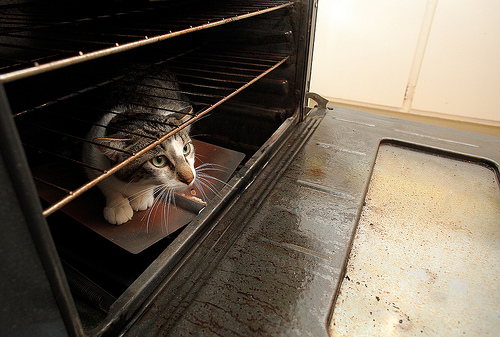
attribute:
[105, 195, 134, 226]
paw — white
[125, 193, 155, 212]
paw — white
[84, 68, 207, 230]
cat — hiding, striped, black, white, looking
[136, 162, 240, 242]
whiskers — white, long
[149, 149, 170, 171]
eye — yellow green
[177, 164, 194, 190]
nose — brown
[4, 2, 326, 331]
oven — off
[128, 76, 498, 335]
door — greasy, dirty, open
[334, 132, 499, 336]
window — greasy, glass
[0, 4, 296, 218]
rack — empty, rusty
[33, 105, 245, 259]
plate — metal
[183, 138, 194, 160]
eye — yellow green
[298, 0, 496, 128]
wall — white